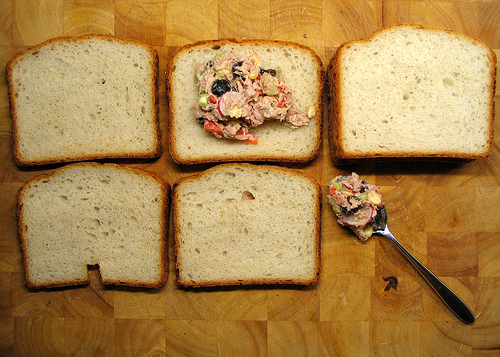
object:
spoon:
[321, 172, 482, 329]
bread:
[17, 158, 168, 290]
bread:
[326, 21, 495, 161]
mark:
[240, 188, 256, 200]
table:
[1, 2, 495, 354]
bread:
[9, 32, 169, 169]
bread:
[165, 37, 324, 164]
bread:
[171, 160, 322, 290]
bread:
[17, 160, 172, 292]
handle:
[383, 227, 477, 326]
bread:
[153, 38, 326, 168]